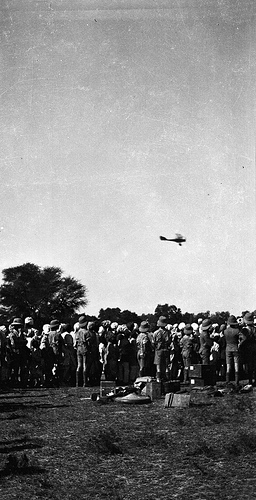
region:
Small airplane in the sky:
[158, 231, 186, 246]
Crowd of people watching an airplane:
[0, 311, 255, 387]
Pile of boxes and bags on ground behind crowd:
[78, 362, 253, 409]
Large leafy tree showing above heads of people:
[0, 261, 88, 330]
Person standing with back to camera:
[222, 313, 241, 386]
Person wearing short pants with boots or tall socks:
[74, 315, 91, 388]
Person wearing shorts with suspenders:
[150, 314, 172, 382]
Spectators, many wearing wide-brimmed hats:
[1, 312, 255, 389]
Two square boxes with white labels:
[187, 362, 217, 387]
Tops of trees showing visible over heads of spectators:
[72, 303, 254, 325]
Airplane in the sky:
[151, 227, 189, 248]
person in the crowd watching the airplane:
[75, 311, 90, 389]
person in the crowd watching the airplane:
[106, 319, 120, 380]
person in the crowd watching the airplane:
[136, 316, 152, 380]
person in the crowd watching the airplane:
[155, 312, 169, 387]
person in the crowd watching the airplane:
[180, 322, 196, 386]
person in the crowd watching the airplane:
[225, 312, 239, 390]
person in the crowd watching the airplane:
[241, 308, 254, 385]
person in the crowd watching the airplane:
[11, 311, 29, 390]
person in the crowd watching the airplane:
[46, 316, 73, 391]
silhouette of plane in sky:
[154, 226, 194, 253]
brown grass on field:
[3, 384, 254, 499]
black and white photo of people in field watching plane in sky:
[0, 2, 253, 495]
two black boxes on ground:
[184, 359, 218, 391]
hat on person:
[75, 313, 88, 330]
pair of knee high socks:
[74, 368, 87, 385]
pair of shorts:
[73, 341, 90, 358]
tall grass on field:
[83, 426, 129, 458]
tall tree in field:
[2, 261, 87, 336]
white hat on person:
[175, 320, 185, 333]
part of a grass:
[198, 461, 200, 463]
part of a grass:
[181, 458, 182, 462]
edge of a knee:
[210, 380, 212, 391]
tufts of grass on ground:
[85, 426, 126, 458]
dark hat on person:
[154, 314, 167, 327]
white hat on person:
[41, 323, 52, 335]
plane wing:
[172, 231, 182, 240]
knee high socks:
[74, 366, 89, 383]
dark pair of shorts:
[73, 344, 90, 363]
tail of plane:
[157, 233, 170, 245]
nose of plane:
[182, 237, 187, 243]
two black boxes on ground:
[181, 359, 218, 387]